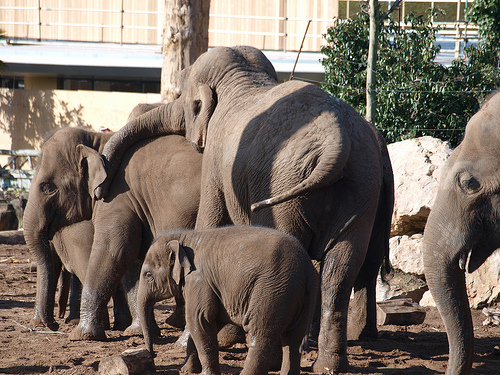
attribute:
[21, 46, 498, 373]
elephant herd — small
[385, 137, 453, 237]
boulder — large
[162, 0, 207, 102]
tree trunk — bare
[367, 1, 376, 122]
fence post — crooked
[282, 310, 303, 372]
elephant leg — grey colored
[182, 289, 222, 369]
elephant leg — grey colored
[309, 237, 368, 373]
elephant leg — grey colored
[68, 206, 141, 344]
elephant leg — grey colored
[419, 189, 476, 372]
elephant trunk — grey colored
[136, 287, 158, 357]
elephant trunk — grey colored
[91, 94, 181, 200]
elephant trunk — grey colored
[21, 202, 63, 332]
elephant trunk — grey colored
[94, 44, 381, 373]
elephant — lit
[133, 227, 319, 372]
elephant — baby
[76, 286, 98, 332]
powder — white